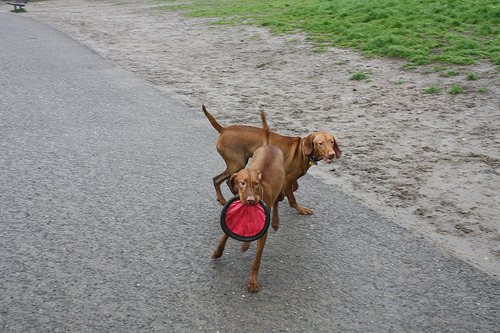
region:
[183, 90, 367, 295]
Two large brown dogs running in the road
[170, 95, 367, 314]
Two brown dogs playing with a frisbee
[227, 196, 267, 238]
The red inner circle on the frisbee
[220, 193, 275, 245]
The outer black ring of the frisbee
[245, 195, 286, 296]
The tall front leg of the brown dog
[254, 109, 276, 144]
The short wagging tail of the dog with a frisbee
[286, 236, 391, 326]
Grey asphalt beneath the dogs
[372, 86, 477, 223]
Brown dirt beside the road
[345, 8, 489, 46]
Short green grass grows on the ground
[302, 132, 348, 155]
Large floppy ears on the dog's head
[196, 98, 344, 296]
two dogs standing on pavement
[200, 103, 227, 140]
the tail of a dog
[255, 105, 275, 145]
the tail of a dog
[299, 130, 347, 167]
the head of a dog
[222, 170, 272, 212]
the head of a dog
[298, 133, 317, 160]
the ear of a dog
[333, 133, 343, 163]
the ear of a dog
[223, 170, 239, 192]
the ear of a dog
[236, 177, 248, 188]
the eye of a dog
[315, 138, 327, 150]
the eye of a dog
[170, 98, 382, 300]
Two brown dogs playing in the road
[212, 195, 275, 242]
A frisbee in the dog's mouth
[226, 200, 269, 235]
A red inner circle on the frisbee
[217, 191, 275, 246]
The black outer circle of the frisbee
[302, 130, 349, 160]
Two large floppy ears on the dog's head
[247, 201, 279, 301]
Tall front leg on the brown dog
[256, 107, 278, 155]
The short wagging tail of the dog with the frisbee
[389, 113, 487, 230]
Brown dirt beside the road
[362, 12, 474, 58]
Short green grass grows on the ground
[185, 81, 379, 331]
there are two dogs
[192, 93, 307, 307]
this dog has a red and black flying disc in its mouth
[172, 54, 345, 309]
the dogs are brown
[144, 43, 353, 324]
the dogs are on asphalt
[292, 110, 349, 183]
this dog has a collar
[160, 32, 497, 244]
there is mud next to the asphalt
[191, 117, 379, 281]
two dogs close together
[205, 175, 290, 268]
dog holds red disc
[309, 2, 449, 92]
green grass behind dogs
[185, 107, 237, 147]
dog has brown tail